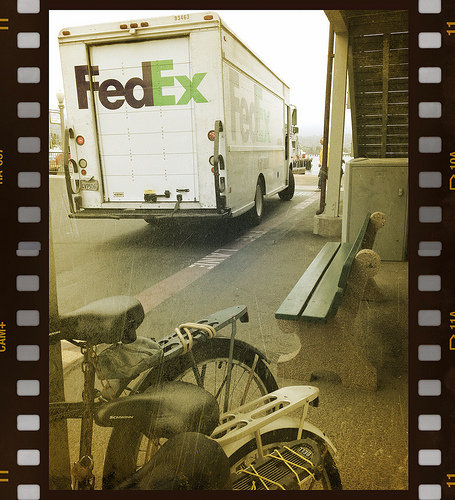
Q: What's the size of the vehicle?
A: Large.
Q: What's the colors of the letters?
A: Black and green.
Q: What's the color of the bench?
A: Green.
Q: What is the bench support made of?
A: Cement.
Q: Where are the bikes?
A: Near bench.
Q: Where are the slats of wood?
A: Bench.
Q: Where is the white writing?
A: Red line.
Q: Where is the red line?
A: On road.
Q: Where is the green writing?
A: On truck.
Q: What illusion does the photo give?
A: Film strip.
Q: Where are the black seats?
A: On bikes.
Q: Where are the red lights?
A: Back of truck.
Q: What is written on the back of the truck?
A: Fedex.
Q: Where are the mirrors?
A: Front of truck.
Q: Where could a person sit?
A: Bench.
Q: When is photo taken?
A: When sun is out.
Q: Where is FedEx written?
A: Back door and side of truck.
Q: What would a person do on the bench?
A: Sit.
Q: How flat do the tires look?
A: Not at all.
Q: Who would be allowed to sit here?
A: Members of the public.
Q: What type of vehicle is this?
A: Truck.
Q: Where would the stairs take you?
A: Above the road.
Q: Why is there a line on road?
A: Fire land.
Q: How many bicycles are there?
A: Two.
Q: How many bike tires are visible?
A: Two.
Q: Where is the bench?
A: Next to the bikes.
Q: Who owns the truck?
A: FedEx.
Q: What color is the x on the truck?
A: Green.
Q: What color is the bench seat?
A: Green.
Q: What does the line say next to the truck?
A: Fire lane.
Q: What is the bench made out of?
A: Concrete.